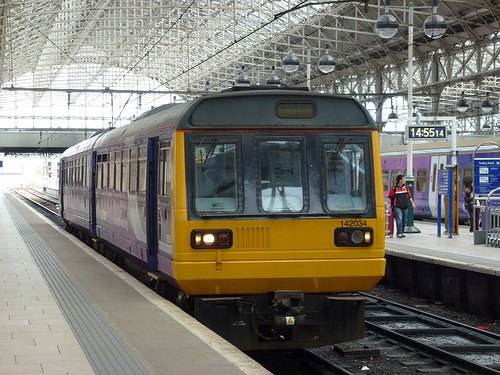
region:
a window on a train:
[187, 137, 234, 217]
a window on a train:
[254, 131, 306, 210]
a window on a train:
[322, 137, 367, 214]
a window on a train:
[416, 165, 429, 189]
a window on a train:
[156, 141, 173, 201]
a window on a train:
[136, 145, 145, 193]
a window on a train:
[128, 146, 135, 186]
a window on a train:
[114, 150, 122, 192]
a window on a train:
[106, 153, 116, 186]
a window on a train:
[96, 158, 102, 187]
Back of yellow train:
[165, 80, 412, 302]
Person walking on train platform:
[383, 162, 425, 255]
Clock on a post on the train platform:
[405, 117, 462, 185]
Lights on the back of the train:
[181, 221, 243, 266]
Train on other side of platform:
[413, 149, 473, 241]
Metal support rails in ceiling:
[20, 11, 238, 78]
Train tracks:
[380, 301, 456, 373]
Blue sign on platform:
[474, 153, 499, 193]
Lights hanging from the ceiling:
[359, 4, 467, 61]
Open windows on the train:
[91, 143, 124, 179]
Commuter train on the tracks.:
[63, 86, 408, 335]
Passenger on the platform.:
[385, 169, 428, 238]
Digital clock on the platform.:
[402, 119, 451, 144]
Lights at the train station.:
[223, 48, 496, 120]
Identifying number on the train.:
[335, 216, 375, 231]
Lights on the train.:
[189, 221, 378, 250]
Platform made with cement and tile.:
[2, 191, 260, 371]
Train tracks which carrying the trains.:
[195, 291, 499, 372]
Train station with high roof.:
[4, 3, 485, 370]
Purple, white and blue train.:
[384, 150, 499, 229]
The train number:
[331, 213, 381, 233]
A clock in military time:
[398, 106, 456, 158]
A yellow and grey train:
[135, 80, 447, 331]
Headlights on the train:
[184, 226, 396, 254]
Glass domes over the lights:
[356, 12, 459, 64]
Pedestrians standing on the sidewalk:
[379, 157, 485, 244]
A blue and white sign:
[470, 138, 497, 203]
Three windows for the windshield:
[181, 116, 379, 218]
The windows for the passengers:
[51, 147, 178, 211]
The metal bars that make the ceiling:
[22, 6, 261, 96]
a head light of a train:
[200, 230, 220, 250]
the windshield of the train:
[182, 119, 376, 216]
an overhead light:
[364, 11, 404, 48]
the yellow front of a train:
[169, 96, 391, 302]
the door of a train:
[140, 130, 164, 277]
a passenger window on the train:
[133, 139, 151, 204]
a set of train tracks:
[344, 276, 498, 373]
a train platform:
[0, 186, 268, 373]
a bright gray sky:
[0, 59, 190, 139]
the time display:
[404, 122, 456, 139]